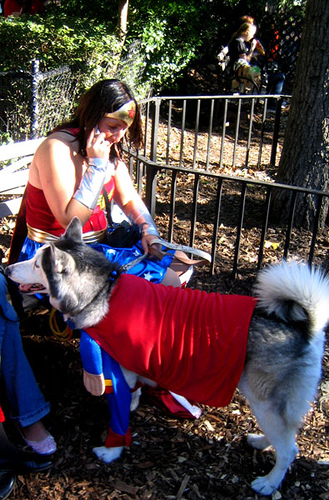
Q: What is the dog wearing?
A: Costume.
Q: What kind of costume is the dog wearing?
A: Superhero.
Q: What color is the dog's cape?
A: Red.